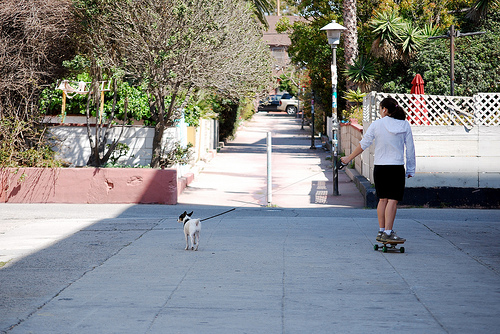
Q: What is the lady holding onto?
A: A leash.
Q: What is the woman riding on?
A: A skateboard.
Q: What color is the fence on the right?
A: White.